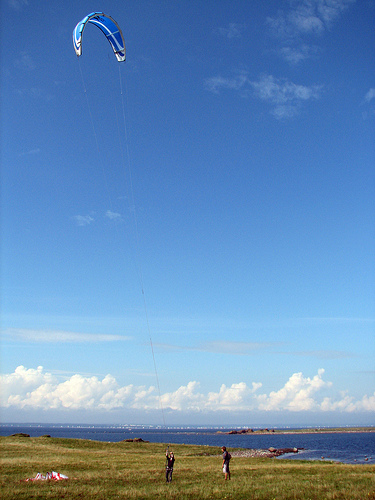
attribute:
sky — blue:
[4, 0, 374, 424]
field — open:
[139, 427, 374, 434]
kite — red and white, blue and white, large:
[74, 12, 127, 63]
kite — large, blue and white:
[72, 9, 129, 66]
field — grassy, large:
[2, 438, 373, 497]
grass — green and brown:
[1, 435, 371, 498]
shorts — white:
[222, 464, 230, 473]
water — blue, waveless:
[1, 429, 373, 463]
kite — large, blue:
[72, 7, 127, 63]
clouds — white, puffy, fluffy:
[1, 364, 373, 413]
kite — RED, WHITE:
[26, 460, 62, 484]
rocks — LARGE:
[4, 430, 38, 440]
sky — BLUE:
[126, 166, 232, 221]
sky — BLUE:
[108, 95, 154, 141]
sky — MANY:
[138, 142, 189, 173]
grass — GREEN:
[273, 474, 327, 493]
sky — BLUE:
[174, 210, 227, 255]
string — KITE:
[138, 308, 167, 434]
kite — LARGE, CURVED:
[77, 18, 128, 64]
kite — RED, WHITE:
[59, 14, 131, 60]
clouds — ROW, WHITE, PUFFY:
[1, 370, 341, 415]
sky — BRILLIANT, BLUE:
[159, 114, 211, 204]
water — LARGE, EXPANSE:
[252, 434, 346, 448]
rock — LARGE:
[111, 430, 149, 446]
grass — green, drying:
[65, 439, 164, 498]